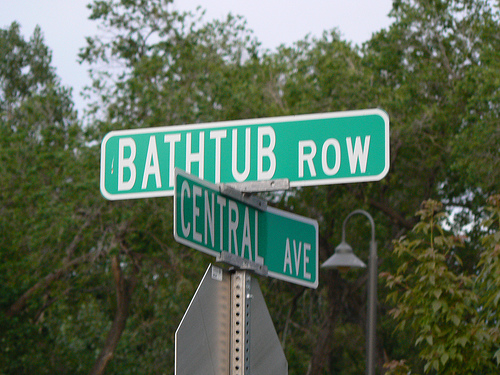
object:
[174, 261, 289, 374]
stop sign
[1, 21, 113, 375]
trees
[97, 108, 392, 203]
street sign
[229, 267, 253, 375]
pole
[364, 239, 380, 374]
lights pole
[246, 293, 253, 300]
nut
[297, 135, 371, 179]
words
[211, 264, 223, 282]
label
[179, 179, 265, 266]
words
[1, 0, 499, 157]
sky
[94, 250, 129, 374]
tree trunk